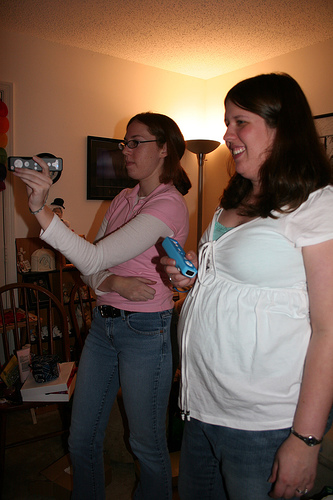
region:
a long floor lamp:
[184, 133, 211, 274]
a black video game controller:
[10, 145, 77, 179]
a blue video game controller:
[160, 232, 202, 288]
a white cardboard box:
[17, 351, 81, 408]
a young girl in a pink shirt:
[21, 111, 193, 458]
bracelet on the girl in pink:
[24, 197, 52, 216]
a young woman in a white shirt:
[171, 79, 325, 498]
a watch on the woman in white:
[285, 420, 329, 450]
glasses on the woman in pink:
[115, 133, 166, 153]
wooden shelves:
[17, 239, 108, 334]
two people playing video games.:
[2, 65, 332, 398]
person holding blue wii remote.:
[158, 233, 201, 290]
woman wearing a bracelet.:
[287, 424, 321, 448]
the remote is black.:
[7, 151, 66, 184]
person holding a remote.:
[5, 150, 67, 182]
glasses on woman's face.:
[114, 132, 162, 152]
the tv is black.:
[80, 129, 146, 207]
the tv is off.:
[82, 131, 135, 207]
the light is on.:
[168, 104, 229, 153]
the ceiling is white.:
[1, 1, 331, 77]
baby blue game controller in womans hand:
[160, 235, 199, 283]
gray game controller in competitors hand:
[6, 153, 64, 173]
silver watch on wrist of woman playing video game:
[286, 425, 327, 450]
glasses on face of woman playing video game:
[115, 137, 166, 150]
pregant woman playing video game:
[176, 63, 331, 489]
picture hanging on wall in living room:
[81, 133, 129, 200]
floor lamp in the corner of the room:
[181, 134, 224, 258]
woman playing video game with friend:
[5, 91, 183, 492]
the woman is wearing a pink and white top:
[59, 181, 194, 321]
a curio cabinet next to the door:
[15, 235, 105, 341]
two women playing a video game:
[7, 69, 331, 498]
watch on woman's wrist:
[286, 423, 331, 450]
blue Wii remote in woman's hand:
[155, 231, 201, 287]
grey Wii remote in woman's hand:
[4, 146, 67, 177]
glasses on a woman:
[112, 135, 162, 149]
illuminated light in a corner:
[170, 109, 228, 261]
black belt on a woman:
[92, 300, 131, 322]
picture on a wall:
[76, 129, 126, 203]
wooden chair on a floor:
[3, 272, 83, 483]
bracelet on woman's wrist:
[28, 202, 49, 217]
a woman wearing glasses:
[99, 109, 188, 196]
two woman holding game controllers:
[14, 71, 316, 257]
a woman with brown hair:
[191, 87, 313, 226]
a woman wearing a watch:
[274, 406, 329, 466]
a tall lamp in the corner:
[170, 100, 228, 252]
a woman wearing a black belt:
[82, 121, 189, 330]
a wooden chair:
[1, 286, 68, 357]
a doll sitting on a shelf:
[36, 186, 71, 244]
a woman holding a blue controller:
[153, 81, 309, 291]